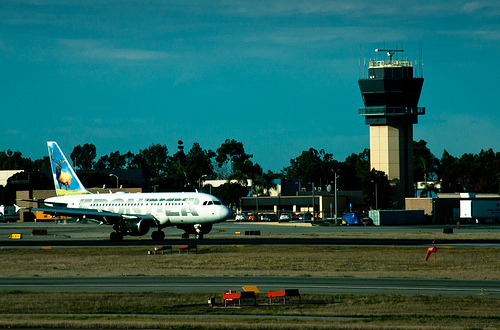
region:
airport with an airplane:
[5, 16, 475, 276]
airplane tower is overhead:
[315, 37, 450, 212]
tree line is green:
[81, 126, 381, 196]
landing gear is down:
[35, 185, 245, 250]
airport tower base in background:
[335, 165, 495, 245]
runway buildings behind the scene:
[200, 150, 330, 245]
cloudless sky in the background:
[15, 15, 480, 135]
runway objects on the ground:
[190, 260, 315, 320]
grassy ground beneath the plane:
[15, 230, 495, 275]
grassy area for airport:
[5, 275, 495, 325]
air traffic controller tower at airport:
[348, 32, 442, 247]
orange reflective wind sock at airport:
[411, 229, 455, 284]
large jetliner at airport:
[20, 127, 257, 268]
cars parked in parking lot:
[232, 202, 339, 237]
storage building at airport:
[362, 198, 445, 243]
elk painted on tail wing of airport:
[41, 136, 98, 198]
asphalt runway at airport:
[67, 258, 398, 327]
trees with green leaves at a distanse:
[81, 136, 376, 204]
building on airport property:
[231, 163, 356, 228]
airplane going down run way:
[0, 177, 498, 248]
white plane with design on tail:
[34, 131, 275, 265]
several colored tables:
[194, 285, 314, 310]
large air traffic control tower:
[337, 25, 448, 210]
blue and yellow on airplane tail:
[41, 150, 82, 198]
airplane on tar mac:
[14, 147, 251, 251]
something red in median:
[422, 240, 454, 275]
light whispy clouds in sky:
[52, 18, 389, 103]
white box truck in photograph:
[441, 194, 498, 222]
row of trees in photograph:
[7, 128, 487, 195]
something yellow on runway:
[5, 220, 35, 257]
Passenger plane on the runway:
[35, 127, 238, 249]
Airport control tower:
[340, 31, 445, 233]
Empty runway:
[0, 256, 492, 318]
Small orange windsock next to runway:
[419, 237, 446, 277]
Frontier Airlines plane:
[37, 130, 232, 245]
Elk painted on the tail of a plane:
[35, 137, 90, 202]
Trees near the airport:
[72, 128, 381, 230]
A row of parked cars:
[227, 205, 332, 227]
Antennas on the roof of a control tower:
[337, 29, 452, 91]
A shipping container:
[454, 193, 499, 223]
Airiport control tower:
[350, 40, 433, 165]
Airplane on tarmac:
[35, 140, 221, 235]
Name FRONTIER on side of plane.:
[80, 195, 217, 223]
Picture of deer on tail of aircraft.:
[45, 131, 71, 187]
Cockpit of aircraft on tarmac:
[185, 185, 225, 220]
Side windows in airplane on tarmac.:
[80, 195, 205, 210]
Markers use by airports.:
[210, 255, 315, 315]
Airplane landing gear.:
[150, 220, 165, 240]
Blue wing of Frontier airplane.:
[20, 201, 130, 222]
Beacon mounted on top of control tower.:
[341, 33, 434, 71]